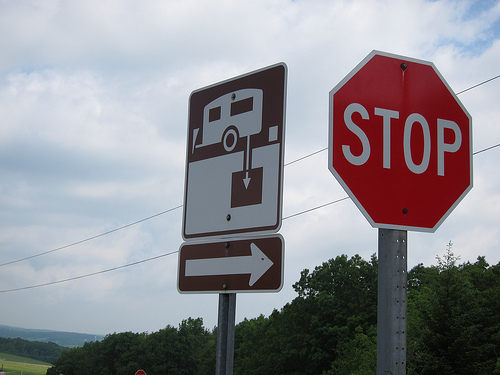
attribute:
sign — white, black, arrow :
[175, 228, 287, 297]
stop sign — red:
[332, 52, 482, 234]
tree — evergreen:
[407, 267, 486, 367]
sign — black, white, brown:
[182, 61, 287, 246]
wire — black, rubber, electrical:
[4, 141, 498, 298]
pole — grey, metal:
[197, 267, 256, 367]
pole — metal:
[212, 291, 237, 373]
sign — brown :
[156, 71, 308, 311]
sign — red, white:
[328, 49, 473, 233]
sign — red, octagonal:
[320, 43, 479, 240]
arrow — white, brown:
[168, 230, 296, 298]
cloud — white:
[1, 66, 177, 168]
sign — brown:
[174, 232, 285, 292]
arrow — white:
[183, 241, 274, 286]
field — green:
[2, 355, 51, 373]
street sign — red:
[318, 49, 477, 249]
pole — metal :
[374, 229, 413, 372]